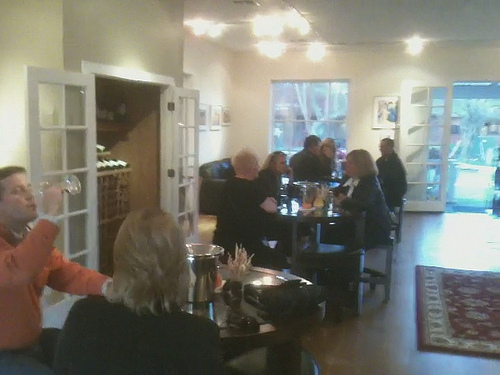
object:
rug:
[412, 259, 499, 364]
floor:
[290, 212, 498, 375]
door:
[397, 78, 450, 213]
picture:
[375, 101, 396, 125]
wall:
[227, 45, 499, 159]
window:
[271, 81, 345, 150]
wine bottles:
[96, 144, 107, 154]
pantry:
[95, 76, 164, 274]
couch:
[197, 156, 234, 214]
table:
[188, 248, 326, 346]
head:
[110, 208, 188, 313]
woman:
[46, 205, 221, 374]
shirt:
[343, 179, 360, 197]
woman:
[329, 147, 392, 242]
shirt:
[213, 177, 265, 245]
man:
[1, 161, 111, 374]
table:
[275, 197, 342, 224]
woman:
[263, 149, 295, 196]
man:
[372, 134, 406, 204]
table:
[325, 169, 351, 183]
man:
[291, 133, 330, 180]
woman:
[321, 135, 338, 174]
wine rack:
[97, 138, 131, 274]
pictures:
[198, 109, 208, 126]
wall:
[182, 29, 227, 163]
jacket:
[340, 178, 395, 241]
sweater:
[3, 219, 109, 349]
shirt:
[55, 293, 220, 374]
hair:
[106, 204, 191, 314]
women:
[212, 148, 278, 256]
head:
[0, 164, 41, 231]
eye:
[11, 185, 22, 196]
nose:
[22, 191, 34, 203]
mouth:
[24, 203, 39, 214]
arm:
[0, 211, 64, 296]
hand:
[41, 181, 65, 217]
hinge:
[166, 100, 174, 112]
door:
[171, 89, 199, 242]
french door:
[22, 64, 99, 329]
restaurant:
[1, 1, 499, 374]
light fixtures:
[185, 0, 330, 62]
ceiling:
[185, 2, 498, 49]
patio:
[432, 153, 499, 199]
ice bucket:
[180, 239, 225, 304]